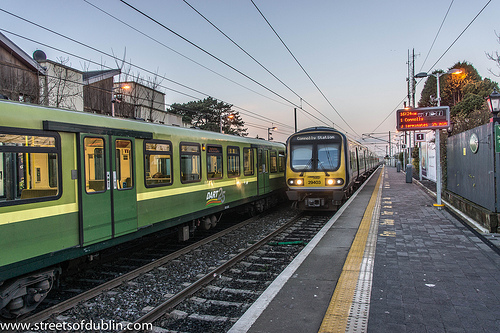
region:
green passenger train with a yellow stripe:
[2, 94, 284, 306]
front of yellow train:
[282, 124, 349, 208]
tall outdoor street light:
[408, 60, 466, 213]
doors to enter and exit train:
[72, 124, 143, 251]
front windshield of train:
[290, 134, 341, 174]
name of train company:
[201, 184, 228, 206]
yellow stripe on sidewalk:
[312, 157, 398, 331]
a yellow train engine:
[281, 125, 360, 207]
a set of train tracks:
[129, 206, 329, 331]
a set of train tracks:
[0, 200, 282, 330]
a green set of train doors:
[78, 130, 139, 241]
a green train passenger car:
[0, 96, 285, 314]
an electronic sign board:
[396, 105, 449, 130]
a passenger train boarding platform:
[230, 163, 499, 331]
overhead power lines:
[1, 0, 365, 145]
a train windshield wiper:
[314, 157, 330, 177]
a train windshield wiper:
[298, 156, 313, 175]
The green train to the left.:
[4, 100, 276, 215]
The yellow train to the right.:
[287, 122, 396, 204]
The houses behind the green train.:
[1, 29, 212, 126]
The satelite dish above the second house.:
[28, 42, 49, 65]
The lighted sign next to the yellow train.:
[396, 105, 467, 143]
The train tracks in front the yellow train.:
[173, 208, 317, 315]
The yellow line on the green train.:
[135, 177, 274, 199]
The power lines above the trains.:
[9, 11, 229, 108]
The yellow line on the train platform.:
[305, 190, 386, 330]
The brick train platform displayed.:
[379, 158, 484, 330]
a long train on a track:
[280, 123, 382, 208]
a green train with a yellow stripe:
[0, 88, 267, 299]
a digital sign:
[395, 99, 451, 137]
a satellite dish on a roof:
[31, 47, 48, 64]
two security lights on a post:
[406, 65, 461, 205]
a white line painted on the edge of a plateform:
[251, 164, 366, 331]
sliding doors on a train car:
[77, 132, 137, 251]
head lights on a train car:
[288, 176, 342, 188]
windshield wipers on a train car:
[295, 159, 332, 178]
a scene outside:
[10, 4, 498, 331]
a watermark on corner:
[1, 315, 176, 331]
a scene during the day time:
[7, 4, 494, 316]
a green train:
[1, 83, 301, 321]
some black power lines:
[2, 0, 399, 144]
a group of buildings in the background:
[2, 30, 275, 153]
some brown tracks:
[136, 195, 339, 331]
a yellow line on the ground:
[315, 159, 400, 331]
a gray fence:
[430, 113, 498, 226]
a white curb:
[217, 150, 386, 331]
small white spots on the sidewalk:
[412, 270, 449, 297]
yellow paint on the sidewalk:
[333, 269, 351, 309]